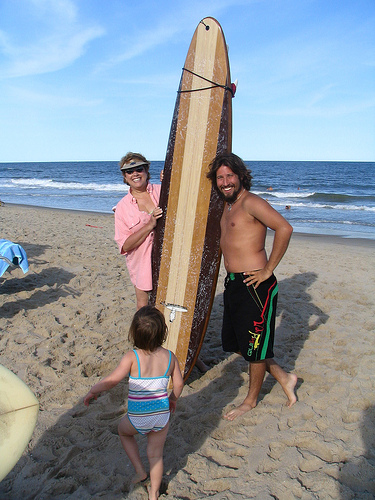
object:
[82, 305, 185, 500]
child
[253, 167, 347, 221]
people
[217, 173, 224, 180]
eye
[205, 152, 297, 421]
man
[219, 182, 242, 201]
beard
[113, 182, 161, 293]
shirt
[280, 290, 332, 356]
shadow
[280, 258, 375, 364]
ground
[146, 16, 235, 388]
surfboard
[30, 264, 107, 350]
sand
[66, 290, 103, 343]
footprint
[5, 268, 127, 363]
beach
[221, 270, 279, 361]
swimsuit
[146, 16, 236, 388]
board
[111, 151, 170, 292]
woman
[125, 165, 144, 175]
sunglass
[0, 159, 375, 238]
ocean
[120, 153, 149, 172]
hat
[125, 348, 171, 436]
suit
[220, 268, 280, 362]
short